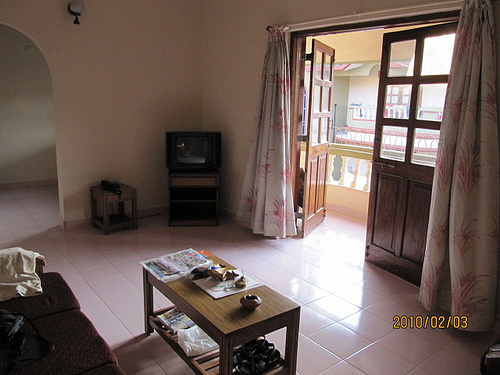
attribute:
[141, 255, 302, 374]
table — wooden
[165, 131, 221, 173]
tv — black, off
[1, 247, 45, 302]
cloth — white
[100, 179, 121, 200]
phone — black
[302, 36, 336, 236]
door — opened, open, brown, wooden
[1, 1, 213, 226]
wall — dark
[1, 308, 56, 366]
wires — black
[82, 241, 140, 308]
tiles — white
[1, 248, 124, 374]
sofa — brown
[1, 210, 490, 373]
floor — white, brown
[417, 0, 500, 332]
curtains — multicolored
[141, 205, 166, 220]
cord — black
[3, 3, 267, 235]
walls — light pink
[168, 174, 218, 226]
cupboard — wooden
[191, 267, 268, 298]
magazine — white